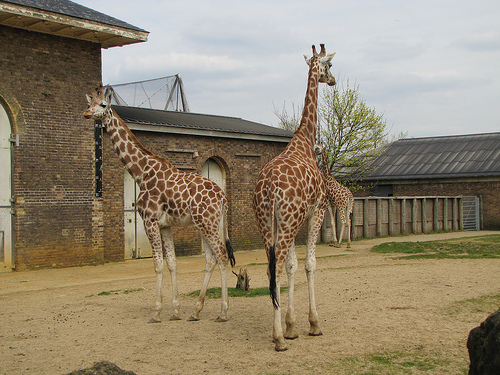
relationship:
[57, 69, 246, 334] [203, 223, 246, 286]
giraffe has tail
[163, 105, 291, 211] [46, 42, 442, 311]
house in background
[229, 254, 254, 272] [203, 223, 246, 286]
tip of tail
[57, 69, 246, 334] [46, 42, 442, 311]
giraffe at zoo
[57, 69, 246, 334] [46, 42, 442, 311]
giraffe in captivity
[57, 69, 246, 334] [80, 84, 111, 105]
giraffe has horn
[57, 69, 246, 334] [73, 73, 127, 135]
giraffe has head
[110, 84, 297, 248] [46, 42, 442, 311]
building in area